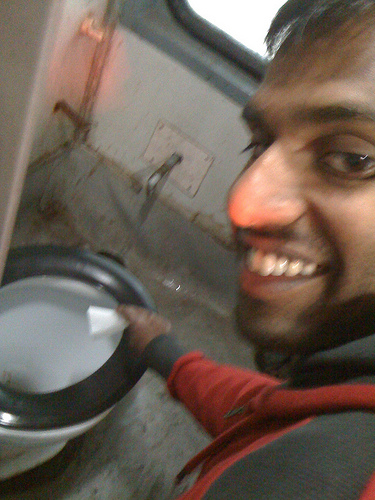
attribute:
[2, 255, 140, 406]
toilet — black, white, here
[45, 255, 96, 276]
seat — black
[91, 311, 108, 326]
cloth — white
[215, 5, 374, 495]
man — smiling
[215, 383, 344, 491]
jacket — red, gray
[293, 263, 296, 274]
tooth — white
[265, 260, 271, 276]
tooth — white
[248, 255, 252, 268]
tooth — white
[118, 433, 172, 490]
floor — gray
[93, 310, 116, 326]
tissue paper — white, here, cloth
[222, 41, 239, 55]
rim — black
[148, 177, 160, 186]
pipe — gray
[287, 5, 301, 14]
hair — dark